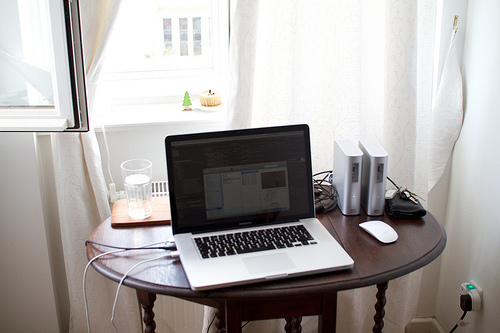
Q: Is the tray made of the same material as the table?
A: Yes, both the tray and the table are made of wood.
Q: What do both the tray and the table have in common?
A: The material, both the tray and the table are wooden.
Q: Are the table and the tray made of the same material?
A: Yes, both the table and the tray are made of wood.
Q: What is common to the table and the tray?
A: The material, both the table and the tray are wooden.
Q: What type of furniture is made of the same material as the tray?
A: The table is made of the same material as the tray.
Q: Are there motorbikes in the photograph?
A: No, there are no motorbikes.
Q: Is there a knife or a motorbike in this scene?
A: No, there are no motorcycles or knives.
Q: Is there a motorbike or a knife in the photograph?
A: No, there are no motorcycles or knives.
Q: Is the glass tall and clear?
A: Yes, the glass is tall and clear.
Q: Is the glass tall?
A: Yes, the glass is tall.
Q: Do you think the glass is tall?
A: Yes, the glass is tall.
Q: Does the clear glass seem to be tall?
A: Yes, the glass is tall.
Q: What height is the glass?
A: The glass is tall.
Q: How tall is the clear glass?
A: The glass is tall.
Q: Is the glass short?
A: No, the glass is tall.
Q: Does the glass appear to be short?
A: No, the glass is tall.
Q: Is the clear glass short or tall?
A: The glass is tall.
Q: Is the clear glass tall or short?
A: The glass is tall.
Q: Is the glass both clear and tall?
A: Yes, the glass is clear and tall.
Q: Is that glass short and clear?
A: No, the glass is clear but tall.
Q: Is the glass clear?
A: Yes, the glass is clear.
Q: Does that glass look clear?
A: Yes, the glass is clear.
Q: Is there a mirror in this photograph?
A: No, there are no mirrors.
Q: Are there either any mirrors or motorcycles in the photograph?
A: No, there are no mirrors or motorcycles.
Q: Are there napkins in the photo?
A: No, there are no napkins.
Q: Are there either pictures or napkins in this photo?
A: No, there are no napkins or pictures.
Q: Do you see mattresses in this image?
A: No, there are no mattresses.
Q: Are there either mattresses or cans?
A: No, there are no mattresses or cans.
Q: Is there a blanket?
A: No, there are no blankets.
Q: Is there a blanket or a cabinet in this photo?
A: No, there are no blankets or cabinets.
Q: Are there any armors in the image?
A: No, there are no armors.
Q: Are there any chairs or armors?
A: No, there are no armors or chairs.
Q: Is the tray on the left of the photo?
A: Yes, the tray is on the left of the image.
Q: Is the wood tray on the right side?
A: No, the tray is on the left of the image.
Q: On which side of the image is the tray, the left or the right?
A: The tray is on the left of the image.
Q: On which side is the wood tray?
A: The tray is on the left of the image.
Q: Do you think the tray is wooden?
A: Yes, the tray is wooden.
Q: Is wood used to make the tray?
A: Yes, the tray is made of wood.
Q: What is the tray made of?
A: The tray is made of wood.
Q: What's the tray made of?
A: The tray is made of wood.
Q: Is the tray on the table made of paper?
A: No, the tray is made of wood.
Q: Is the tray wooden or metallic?
A: The tray is wooden.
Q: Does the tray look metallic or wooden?
A: The tray is wooden.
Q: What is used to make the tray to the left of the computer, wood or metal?
A: The tray is made of wood.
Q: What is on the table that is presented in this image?
A: The tray is on the table.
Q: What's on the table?
A: The tray is on the table.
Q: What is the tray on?
A: The tray is on the table.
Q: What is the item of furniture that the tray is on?
A: The piece of furniture is a table.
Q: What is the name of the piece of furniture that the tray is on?
A: The piece of furniture is a table.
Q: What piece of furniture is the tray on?
A: The tray is on the table.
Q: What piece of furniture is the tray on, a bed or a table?
A: The tray is on a table.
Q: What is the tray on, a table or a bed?
A: The tray is on a table.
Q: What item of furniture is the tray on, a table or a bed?
A: The tray is on a table.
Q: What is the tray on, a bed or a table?
A: The tray is on a table.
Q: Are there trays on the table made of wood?
A: Yes, there is a tray on the table.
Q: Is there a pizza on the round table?
A: No, there is a tray on the table.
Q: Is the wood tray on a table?
A: Yes, the tray is on a table.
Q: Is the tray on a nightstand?
A: No, the tray is on a table.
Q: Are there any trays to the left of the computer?
A: Yes, there is a tray to the left of the computer.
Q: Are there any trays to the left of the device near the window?
A: Yes, there is a tray to the left of the computer.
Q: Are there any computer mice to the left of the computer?
A: No, there is a tray to the left of the computer.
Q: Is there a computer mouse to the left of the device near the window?
A: No, there is a tray to the left of the computer.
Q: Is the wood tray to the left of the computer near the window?
A: Yes, the tray is to the left of the computer.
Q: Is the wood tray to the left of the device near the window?
A: Yes, the tray is to the left of the computer.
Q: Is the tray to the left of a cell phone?
A: No, the tray is to the left of the computer.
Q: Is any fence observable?
A: No, there are no fences.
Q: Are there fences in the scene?
A: No, there are no fences.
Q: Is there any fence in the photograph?
A: No, there are no fences.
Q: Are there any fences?
A: No, there are no fences.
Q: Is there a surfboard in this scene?
A: No, there are no surfboards.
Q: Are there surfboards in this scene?
A: No, there are no surfboards.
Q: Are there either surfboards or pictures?
A: No, there are no surfboards or pictures.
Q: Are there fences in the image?
A: No, there are no fences.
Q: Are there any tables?
A: Yes, there is a table.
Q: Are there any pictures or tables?
A: Yes, there is a table.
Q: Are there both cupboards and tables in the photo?
A: No, there is a table but no cupboards.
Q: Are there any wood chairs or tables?
A: Yes, there is a wood table.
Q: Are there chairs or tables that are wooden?
A: Yes, the table is wooden.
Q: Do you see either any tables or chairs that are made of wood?
A: Yes, the table is made of wood.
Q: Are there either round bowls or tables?
A: Yes, there is a round table.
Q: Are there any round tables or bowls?
A: Yes, there is a round table.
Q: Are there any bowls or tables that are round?
A: Yes, the table is round.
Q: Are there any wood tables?
A: Yes, there is a wood table.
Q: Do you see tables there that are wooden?
A: Yes, there is a table that is wooden.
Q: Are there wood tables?
A: Yes, there is a table that is made of wood.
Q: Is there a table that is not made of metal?
A: Yes, there is a table that is made of wood.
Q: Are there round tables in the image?
A: Yes, there is a round table.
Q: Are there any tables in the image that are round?
A: Yes, there is a table that is round.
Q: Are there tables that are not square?
A: Yes, there is a round table.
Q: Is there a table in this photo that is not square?
A: Yes, there is a round table.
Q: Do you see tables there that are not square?
A: Yes, there is a round table.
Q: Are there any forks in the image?
A: No, there are no forks.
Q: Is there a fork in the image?
A: No, there are no forks.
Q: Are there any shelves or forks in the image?
A: No, there are no forks or shelves.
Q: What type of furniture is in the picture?
A: The furniture is a table.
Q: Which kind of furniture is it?
A: The piece of furniture is a table.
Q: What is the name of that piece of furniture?
A: This is a table.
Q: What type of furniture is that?
A: This is a table.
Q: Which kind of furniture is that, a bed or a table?
A: This is a table.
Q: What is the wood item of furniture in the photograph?
A: The piece of furniture is a table.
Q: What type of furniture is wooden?
A: The furniture is a table.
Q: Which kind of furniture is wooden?
A: The furniture is a table.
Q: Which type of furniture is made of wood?
A: The furniture is a table.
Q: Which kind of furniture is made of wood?
A: The furniture is a table.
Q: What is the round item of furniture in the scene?
A: The piece of furniture is a table.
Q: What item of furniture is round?
A: The piece of furniture is a table.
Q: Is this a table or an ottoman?
A: This is a table.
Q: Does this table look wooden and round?
A: Yes, the table is wooden and round.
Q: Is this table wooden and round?
A: Yes, the table is wooden and round.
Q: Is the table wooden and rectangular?
A: No, the table is wooden but round.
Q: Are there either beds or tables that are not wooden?
A: No, there is a table but it is wooden.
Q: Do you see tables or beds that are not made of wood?
A: No, there is a table but it is made of wood.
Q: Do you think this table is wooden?
A: Yes, the table is wooden.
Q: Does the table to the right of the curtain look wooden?
A: Yes, the table is wooden.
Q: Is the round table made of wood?
A: Yes, the table is made of wood.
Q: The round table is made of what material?
A: The table is made of wood.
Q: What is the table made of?
A: The table is made of wood.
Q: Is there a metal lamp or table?
A: No, there is a table but it is wooden.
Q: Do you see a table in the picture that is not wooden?
A: No, there is a table but it is wooden.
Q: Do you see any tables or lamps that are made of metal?
A: No, there is a table but it is made of wood.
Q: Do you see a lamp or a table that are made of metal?
A: No, there is a table but it is made of wood.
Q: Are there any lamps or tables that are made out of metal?
A: No, there is a table but it is made of wood.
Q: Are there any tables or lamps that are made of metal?
A: No, there is a table but it is made of wood.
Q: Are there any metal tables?
A: No, there is a table but it is made of wood.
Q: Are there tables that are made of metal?
A: No, there is a table but it is made of wood.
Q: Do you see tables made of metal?
A: No, there is a table but it is made of wood.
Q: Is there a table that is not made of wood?
A: No, there is a table but it is made of wood.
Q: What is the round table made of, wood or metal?
A: The table is made of wood.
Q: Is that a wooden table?
A: Yes, that is a wooden table.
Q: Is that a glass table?
A: No, that is a wooden table.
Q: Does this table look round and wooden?
A: Yes, the table is round and wooden.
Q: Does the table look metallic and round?
A: No, the table is round but wooden.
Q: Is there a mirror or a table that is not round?
A: No, there is a table but it is round.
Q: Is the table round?
A: Yes, the table is round.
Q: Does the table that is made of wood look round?
A: Yes, the table is round.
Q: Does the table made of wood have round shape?
A: Yes, the table is round.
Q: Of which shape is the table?
A: The table is round.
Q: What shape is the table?
A: The table is round.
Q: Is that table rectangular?
A: No, the table is round.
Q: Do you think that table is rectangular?
A: No, the table is round.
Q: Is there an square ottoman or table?
A: No, there is a table but it is round.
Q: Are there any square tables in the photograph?
A: No, there is a table but it is round.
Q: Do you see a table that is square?
A: No, there is a table but it is round.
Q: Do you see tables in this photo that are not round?
A: No, there is a table but it is round.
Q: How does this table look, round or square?
A: The table is round.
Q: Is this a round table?
A: Yes, this is a round table.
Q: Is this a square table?
A: No, this is a round table.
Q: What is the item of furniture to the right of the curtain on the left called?
A: The piece of furniture is a table.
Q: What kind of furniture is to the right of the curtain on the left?
A: The piece of furniture is a table.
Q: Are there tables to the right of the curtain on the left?
A: Yes, there is a table to the right of the curtain.